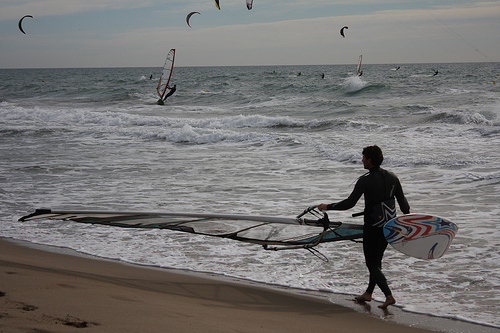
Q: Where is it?
A: This is at the ocean.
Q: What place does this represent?
A: It represents the ocean.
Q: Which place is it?
A: It is an ocean.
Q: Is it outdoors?
A: Yes, it is outdoors.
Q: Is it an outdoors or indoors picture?
A: It is outdoors.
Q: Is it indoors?
A: No, it is outdoors.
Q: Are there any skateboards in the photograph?
A: No, there are no skateboards.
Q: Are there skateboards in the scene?
A: No, there are no skateboards.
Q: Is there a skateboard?
A: No, there are no skateboards.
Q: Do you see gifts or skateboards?
A: No, there are no skateboards or gifts.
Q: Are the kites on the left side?
A: Yes, the kites are on the left of the image.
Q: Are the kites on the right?
A: No, the kites are on the left of the image.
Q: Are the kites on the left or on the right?
A: The kites are on the left of the image.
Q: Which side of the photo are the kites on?
A: The kites are on the left of the image.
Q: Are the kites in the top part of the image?
A: Yes, the kites are in the top of the image.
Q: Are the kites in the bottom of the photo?
A: No, the kites are in the top of the image.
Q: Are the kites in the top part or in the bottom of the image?
A: The kites are in the top of the image.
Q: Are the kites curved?
A: Yes, the kites are curved.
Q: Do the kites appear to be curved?
A: Yes, the kites are curved.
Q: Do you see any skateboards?
A: No, there are no skateboards.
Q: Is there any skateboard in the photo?
A: No, there are no skateboards.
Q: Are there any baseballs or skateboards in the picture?
A: No, there are no skateboards or baseballs.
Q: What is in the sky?
A: The clouds are in the sky.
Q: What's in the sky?
A: The clouds are in the sky.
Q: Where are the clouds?
A: The clouds are in the sky.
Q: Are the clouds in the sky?
A: Yes, the clouds are in the sky.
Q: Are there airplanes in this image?
A: No, there are no airplanes.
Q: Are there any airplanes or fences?
A: No, there are no airplanes or fences.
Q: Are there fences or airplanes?
A: No, there are no airplanes or fences.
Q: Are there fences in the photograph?
A: No, there are no fences.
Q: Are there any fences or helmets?
A: No, there are no fences or helmets.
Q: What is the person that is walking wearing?
A: The person is wearing a wet suit.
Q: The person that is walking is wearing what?
A: The person is wearing a wet suit.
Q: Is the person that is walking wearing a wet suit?
A: Yes, the person is wearing a wet suit.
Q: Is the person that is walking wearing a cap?
A: No, the person is wearing a wet suit.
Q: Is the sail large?
A: Yes, the sail is large.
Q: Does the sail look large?
A: Yes, the sail is large.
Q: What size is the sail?
A: The sail is large.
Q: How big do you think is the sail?
A: The sail is large.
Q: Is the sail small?
A: No, the sail is large.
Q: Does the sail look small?
A: No, the sail is large.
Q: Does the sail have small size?
A: No, the sail is large.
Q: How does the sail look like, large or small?
A: The sail is large.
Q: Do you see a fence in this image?
A: No, there are no fences.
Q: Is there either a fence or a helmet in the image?
A: No, there are no fences or helmets.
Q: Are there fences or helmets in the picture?
A: No, there are no fences or helmets.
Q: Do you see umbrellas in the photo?
A: No, there are no umbrellas.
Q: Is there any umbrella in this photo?
A: No, there are no umbrellas.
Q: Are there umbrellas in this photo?
A: No, there are no umbrellas.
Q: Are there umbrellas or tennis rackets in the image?
A: No, there are no umbrellas or tennis rackets.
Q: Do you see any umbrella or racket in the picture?
A: No, there are no umbrellas or rackets.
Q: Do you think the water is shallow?
A: Yes, the water is shallow.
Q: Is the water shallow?
A: Yes, the water is shallow.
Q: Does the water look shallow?
A: Yes, the water is shallow.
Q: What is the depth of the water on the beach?
A: The water is shallow.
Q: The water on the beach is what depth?
A: The water is shallow.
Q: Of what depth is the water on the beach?
A: The water is shallow.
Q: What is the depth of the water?
A: The water is shallow.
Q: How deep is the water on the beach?
A: The water is shallow.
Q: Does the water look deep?
A: No, the water is shallow.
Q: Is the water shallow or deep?
A: The water is shallow.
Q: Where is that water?
A: The water is on the beach.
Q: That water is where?
A: The water is on the beach.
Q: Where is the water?
A: The water is on the beach.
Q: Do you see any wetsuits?
A: Yes, there is a wetsuit.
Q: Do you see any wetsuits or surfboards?
A: Yes, there is a wetsuit.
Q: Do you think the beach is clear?
A: Yes, the beach is clear.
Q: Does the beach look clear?
A: Yes, the beach is clear.